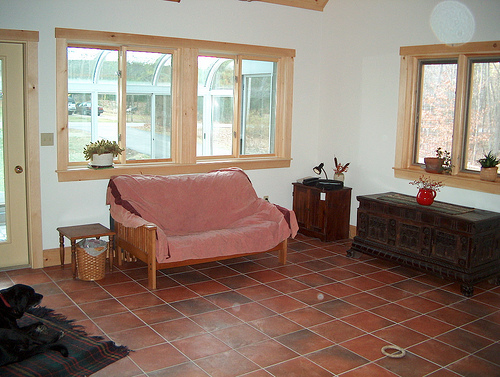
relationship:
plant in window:
[83, 139, 124, 168] [67, 44, 173, 164]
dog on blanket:
[0, 284, 68, 365] [1, 308, 138, 376]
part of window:
[143, 105, 165, 146] [67, 44, 173, 164]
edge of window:
[120, 159, 177, 170] [67, 44, 173, 164]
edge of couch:
[160, 217, 280, 248] [105, 166, 304, 290]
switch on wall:
[40, 133, 54, 145] [37, 8, 330, 267]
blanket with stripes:
[1, 308, 138, 376] [22, 310, 119, 364]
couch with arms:
[105, 166, 304, 290] [112, 198, 296, 257]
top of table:
[57, 223, 117, 239] [55, 222, 118, 272]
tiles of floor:
[178, 308, 234, 368] [141, 293, 358, 369]